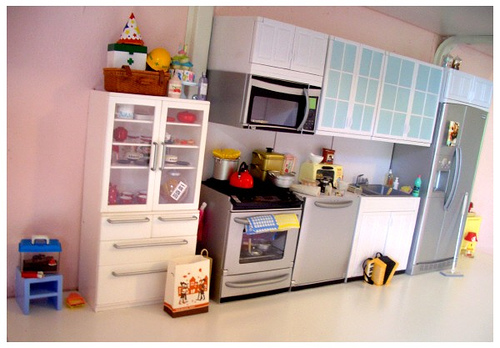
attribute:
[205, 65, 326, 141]
microwave — black, built in, silver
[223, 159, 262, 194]
tea kettle — red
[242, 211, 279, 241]
towel — blue, white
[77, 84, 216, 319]
cabinet — filled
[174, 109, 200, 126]
bowl — red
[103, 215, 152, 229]
handle — silver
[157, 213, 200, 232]
handle — silver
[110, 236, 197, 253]
handle — silver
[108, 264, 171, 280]
handle — silver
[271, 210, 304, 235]
towel — yellow, white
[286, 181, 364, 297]
dishwasher — silver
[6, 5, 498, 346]
kitchen — colorful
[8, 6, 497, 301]
wall — pink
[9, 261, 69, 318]
stool — blue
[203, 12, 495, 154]
cabinets — white, pale mint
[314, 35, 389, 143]
door — clear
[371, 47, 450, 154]
door — clear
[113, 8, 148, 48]
party hat — red,white,and blue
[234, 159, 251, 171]
handle — black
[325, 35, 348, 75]
square — blue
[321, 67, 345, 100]
square — blue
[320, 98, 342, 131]
square — blue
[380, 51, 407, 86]
square — blue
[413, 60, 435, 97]
square — blue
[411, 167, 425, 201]
bottle — blue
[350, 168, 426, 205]
sink — silver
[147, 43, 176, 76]
hard hat — yellow